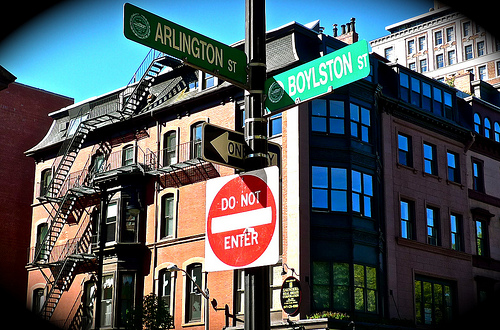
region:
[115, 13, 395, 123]
two green and white street signs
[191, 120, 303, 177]
a black and white sign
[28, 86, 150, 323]
fire escape on building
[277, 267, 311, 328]
an oval shaped sign on building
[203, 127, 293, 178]
a black sign with white arrow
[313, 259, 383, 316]
trees reflected in window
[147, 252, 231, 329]
a street lamp by building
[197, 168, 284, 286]
a sign indicating do not enter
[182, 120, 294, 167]
a one way sign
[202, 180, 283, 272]
The white and red street sign.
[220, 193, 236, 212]
The word Do on the white and red sign.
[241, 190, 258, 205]
The word Not on the street sign.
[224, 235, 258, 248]
The word Enter on the street sign.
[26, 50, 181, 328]
The stairs of the fire escape on the building.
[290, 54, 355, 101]
The word Boylston on the street sign.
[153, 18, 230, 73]
The word Arlington on the street sign.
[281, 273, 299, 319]
The black sign on the building.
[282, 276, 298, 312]
The writing on the black sign on the building.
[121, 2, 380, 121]
two green and white street signs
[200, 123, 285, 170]
black and white street sign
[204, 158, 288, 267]
red and white traffic sign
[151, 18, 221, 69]
white lettering on green background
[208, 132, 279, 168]
white arrow on black background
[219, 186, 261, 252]
white lettering on red background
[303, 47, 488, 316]
reflective windows on brick building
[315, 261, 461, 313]
trees reflected on the windows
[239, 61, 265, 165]
brackets attaching signs to pole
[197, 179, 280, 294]
a sign on the board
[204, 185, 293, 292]
red board with white text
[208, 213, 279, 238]
a white line in between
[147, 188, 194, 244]
a window in the building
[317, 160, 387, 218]
a blue windows in the buildng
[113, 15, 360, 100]
two boards in the top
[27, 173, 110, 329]
steps to the building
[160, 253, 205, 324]
door of the building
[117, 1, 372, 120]
green signs with white lettering are on the pole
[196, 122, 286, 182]
the black sign has a white arrow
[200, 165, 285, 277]
the square sign has a red circle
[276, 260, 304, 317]
a light fixture is over an oval sign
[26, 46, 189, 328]
fire escapes are on the side of the building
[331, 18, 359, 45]
chimney stacks are on the roof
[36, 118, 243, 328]
arched windows are on the building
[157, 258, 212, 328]
a street lamp is on a pole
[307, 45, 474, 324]
the building has double hung windows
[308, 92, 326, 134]
a window on a building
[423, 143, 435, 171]
a window on a building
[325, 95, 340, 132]
a window on a building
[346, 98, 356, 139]
a window on a building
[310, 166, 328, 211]
a window on a building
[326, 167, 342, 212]
a window on a building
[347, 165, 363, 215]
a window on a building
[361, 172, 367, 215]
a window on a building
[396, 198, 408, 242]
a window on a building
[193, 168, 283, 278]
Red and white sign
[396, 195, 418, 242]
Window of a building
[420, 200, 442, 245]
Window of a building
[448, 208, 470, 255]
Window of a building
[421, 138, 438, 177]
Window of a building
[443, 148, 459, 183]
Window of a building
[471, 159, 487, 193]
Window of a building